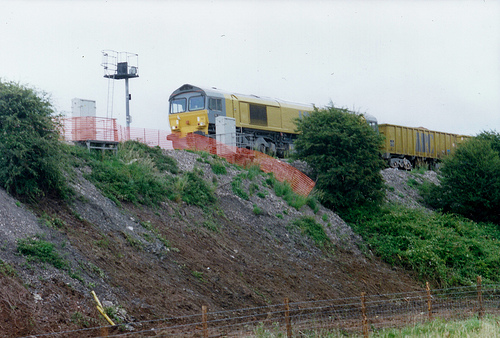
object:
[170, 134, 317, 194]
fence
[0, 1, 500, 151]
sky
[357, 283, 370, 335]
post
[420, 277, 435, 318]
post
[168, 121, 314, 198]
orange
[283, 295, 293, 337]
wood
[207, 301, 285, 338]
wire.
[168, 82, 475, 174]
train.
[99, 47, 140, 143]
tower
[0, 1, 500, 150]
gray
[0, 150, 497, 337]
dirt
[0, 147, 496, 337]
rocks.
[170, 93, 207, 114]
windshield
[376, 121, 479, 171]
car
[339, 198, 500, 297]
weeds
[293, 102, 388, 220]
bushes.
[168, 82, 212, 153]
front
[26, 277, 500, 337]
fence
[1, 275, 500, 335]
bottom.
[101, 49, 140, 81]
top.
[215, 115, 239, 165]
kind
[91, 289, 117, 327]
stick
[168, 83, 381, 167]
car.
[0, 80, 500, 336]
yard.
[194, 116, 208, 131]
headlights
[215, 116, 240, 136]
metal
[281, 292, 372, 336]
two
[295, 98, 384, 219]
tree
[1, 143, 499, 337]
slope.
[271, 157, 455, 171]
tracks.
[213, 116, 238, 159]
container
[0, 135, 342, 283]
grass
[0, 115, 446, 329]
down.